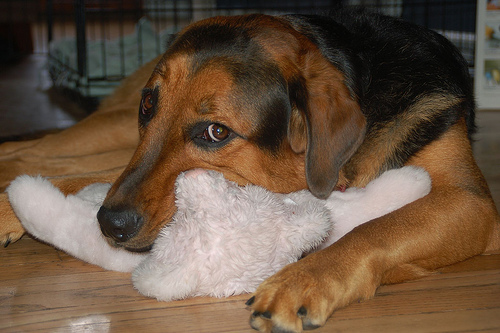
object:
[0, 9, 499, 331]
dog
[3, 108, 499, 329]
floor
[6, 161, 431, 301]
teddy bear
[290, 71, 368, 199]
ear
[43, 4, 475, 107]
cage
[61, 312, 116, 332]
reflection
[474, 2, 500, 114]
picture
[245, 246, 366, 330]
paw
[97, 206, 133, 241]
nose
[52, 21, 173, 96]
cloth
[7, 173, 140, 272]
arm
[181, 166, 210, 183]
nose